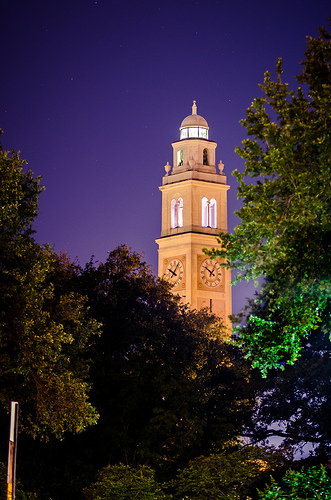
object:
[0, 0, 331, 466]
sky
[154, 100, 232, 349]
tower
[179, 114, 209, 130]
dome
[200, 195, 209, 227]
window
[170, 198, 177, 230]
window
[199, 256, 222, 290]
clock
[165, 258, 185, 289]
clock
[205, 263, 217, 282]
dial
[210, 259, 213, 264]
roman numerals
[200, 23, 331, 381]
tree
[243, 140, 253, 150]
leaf